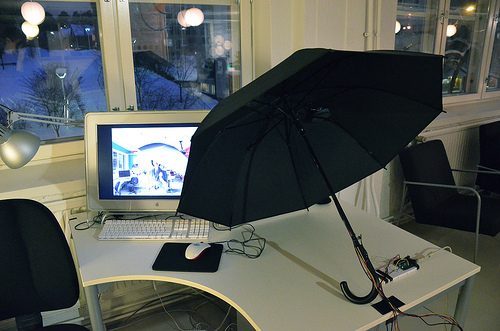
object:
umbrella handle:
[339, 245, 382, 306]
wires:
[374, 245, 463, 331]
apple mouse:
[185, 243, 211, 260]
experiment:
[0, 112, 500, 329]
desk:
[2, 196, 482, 330]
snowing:
[3, 53, 104, 114]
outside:
[1, 0, 233, 139]